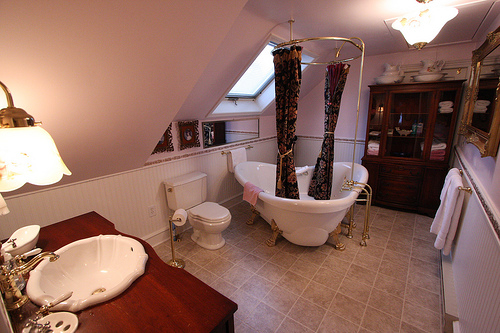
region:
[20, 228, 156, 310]
Decorative round bathroom sink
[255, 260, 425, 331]
Tiled bathroom floor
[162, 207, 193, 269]
Toilet paper dispenser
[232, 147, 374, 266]
Large bathtub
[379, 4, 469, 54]
Overhead lighting hanging from the ceiling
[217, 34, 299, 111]
Large skylight in the roof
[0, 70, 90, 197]
Lampshade of a table lamp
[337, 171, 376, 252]
Plumbing for large bathtub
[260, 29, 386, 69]
Hanging shower curtain rack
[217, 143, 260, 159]
Towel holders mounted on the wall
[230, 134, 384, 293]
Unusual heart shaped bathtub.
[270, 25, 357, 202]
Shower curtain ring over tub.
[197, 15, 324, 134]
Sky light built into roof.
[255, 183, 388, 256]
Gold claw feet pipes.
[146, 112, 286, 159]
Pictures beside long mirror.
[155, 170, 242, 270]
White toilet gold paper holder.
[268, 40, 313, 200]
Gold tassel holds shower curtain .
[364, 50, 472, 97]
Two pitcher bowl sets.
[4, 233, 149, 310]
Gold faucets white sink basin.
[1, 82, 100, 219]
Tulip lamp shade above sink.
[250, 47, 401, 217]
set of curtains in the tub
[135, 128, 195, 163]
two picture frames on the ledge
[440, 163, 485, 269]
white towels are towel bar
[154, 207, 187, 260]
roll of toilet paper on stand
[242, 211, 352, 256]
gold legs on the tub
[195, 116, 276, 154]
long mirror under the window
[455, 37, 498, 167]
gold frame around large mirror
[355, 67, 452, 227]
china hutch in the bathroom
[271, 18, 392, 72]
shower rod is a gold circle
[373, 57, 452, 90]
two wash basins on top of china hutch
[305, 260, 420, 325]
brown tiles on a bathroom floor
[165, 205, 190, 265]
stand of toilet paper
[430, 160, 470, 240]
towel hanging from a rack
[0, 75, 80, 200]
glass lamp turned on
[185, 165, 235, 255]
white porcelain toilet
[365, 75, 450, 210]
hutch for extra towels and bathroom supplies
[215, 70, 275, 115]
sky light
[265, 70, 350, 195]
tied shower curtains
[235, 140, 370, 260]
decorative tub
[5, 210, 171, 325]
vanity sink with a wood top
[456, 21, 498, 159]
framed mirror on wall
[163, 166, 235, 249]
white toilet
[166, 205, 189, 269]
brass toilet paper holder on stand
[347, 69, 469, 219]
free standing dark wood cabinet against wall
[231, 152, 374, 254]
white claw foot bathtub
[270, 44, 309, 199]
floral shower curtain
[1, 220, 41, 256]
white soap dish sitting on sink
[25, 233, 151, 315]
white scallop sink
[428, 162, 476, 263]
white towels haning on brass towel bar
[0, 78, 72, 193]
light fixture